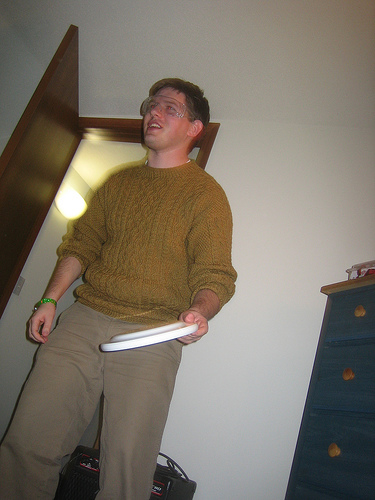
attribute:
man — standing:
[3, 77, 238, 499]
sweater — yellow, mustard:
[58, 158, 238, 321]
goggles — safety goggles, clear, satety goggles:
[140, 93, 198, 130]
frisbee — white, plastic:
[99, 319, 199, 354]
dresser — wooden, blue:
[280, 275, 373, 499]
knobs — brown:
[325, 302, 367, 457]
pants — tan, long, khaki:
[2, 301, 187, 499]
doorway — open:
[1, 127, 198, 469]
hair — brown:
[147, 74, 211, 158]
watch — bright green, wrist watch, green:
[31, 297, 58, 310]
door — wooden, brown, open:
[1, 24, 80, 323]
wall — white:
[4, 7, 373, 499]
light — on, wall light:
[55, 187, 88, 221]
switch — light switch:
[13, 274, 26, 298]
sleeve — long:
[186, 180, 238, 313]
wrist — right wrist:
[36, 292, 59, 312]